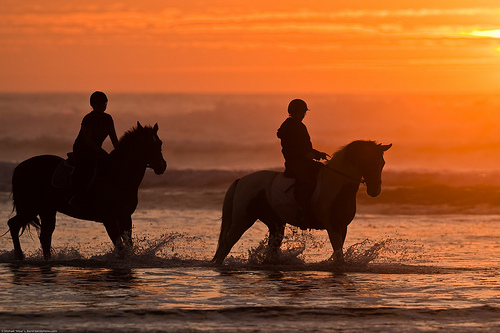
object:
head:
[286, 98, 309, 113]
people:
[276, 97, 328, 222]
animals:
[208, 138, 394, 268]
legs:
[326, 227, 347, 273]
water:
[129, 226, 402, 298]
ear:
[383, 140, 393, 151]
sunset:
[332, 0, 500, 108]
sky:
[4, 0, 500, 96]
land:
[73, 294, 496, 333]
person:
[275, 96, 333, 227]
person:
[70, 89, 123, 202]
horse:
[206, 138, 392, 272]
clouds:
[7, 7, 493, 60]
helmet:
[285, 98, 310, 114]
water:
[2, 217, 496, 329]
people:
[70, 90, 121, 191]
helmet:
[89, 90, 109, 104]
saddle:
[270, 166, 321, 206]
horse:
[5, 120, 169, 267]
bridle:
[362, 176, 383, 187]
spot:
[328, 183, 357, 229]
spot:
[243, 186, 283, 223]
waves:
[152, 152, 488, 208]